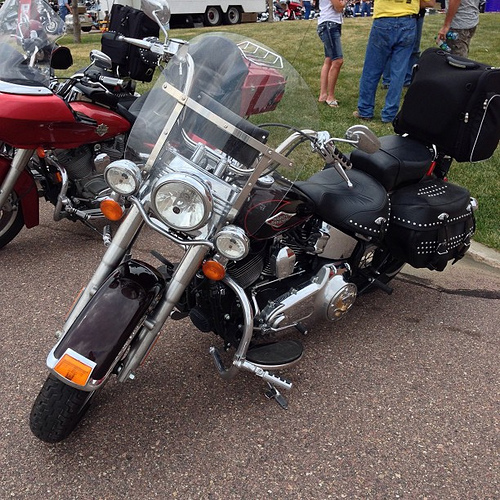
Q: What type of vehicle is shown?
A: Motorcycle.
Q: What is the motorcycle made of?
A: Metal.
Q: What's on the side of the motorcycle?
A: Saddlebag.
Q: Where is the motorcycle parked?
A: Curb.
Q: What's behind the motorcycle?
A: Grass.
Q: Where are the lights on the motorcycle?
A: On the front.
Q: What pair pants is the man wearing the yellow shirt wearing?
A: Jeans.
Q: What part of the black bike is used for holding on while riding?
A: The handlebars.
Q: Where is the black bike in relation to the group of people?
A: In the front.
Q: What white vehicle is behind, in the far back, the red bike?
A: A bus.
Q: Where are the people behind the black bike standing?
A: The grass.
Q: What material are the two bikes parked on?
A: Asphalt.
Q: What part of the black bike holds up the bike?
A: The kickstand.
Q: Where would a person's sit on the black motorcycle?
A: The seat.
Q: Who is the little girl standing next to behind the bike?
A: The man wearing the yellow shirt.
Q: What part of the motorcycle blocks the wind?
A: Windshield.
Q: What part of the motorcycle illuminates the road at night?
A: The headlight.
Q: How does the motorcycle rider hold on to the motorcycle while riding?
A: With the handlebars.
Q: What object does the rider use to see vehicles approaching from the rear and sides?
A: The mirrors.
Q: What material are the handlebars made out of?
A: Metal.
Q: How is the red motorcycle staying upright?
A: Kickstand.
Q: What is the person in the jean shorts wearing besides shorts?
A: Teeshirt and sandals.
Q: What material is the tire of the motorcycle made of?
A: Rubber.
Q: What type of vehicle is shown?
A: A motorcycle.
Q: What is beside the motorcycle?
A: Another motorcycle.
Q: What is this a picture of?
A: Motorcycle.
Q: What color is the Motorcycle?
A: Black.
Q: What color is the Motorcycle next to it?
A: Red.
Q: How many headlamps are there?
A: 3.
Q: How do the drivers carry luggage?
A: Luggage Racks.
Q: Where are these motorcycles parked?
A: On Pavement.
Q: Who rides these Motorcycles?
A: Men and Women.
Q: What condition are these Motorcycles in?
A: Very Good Condition.